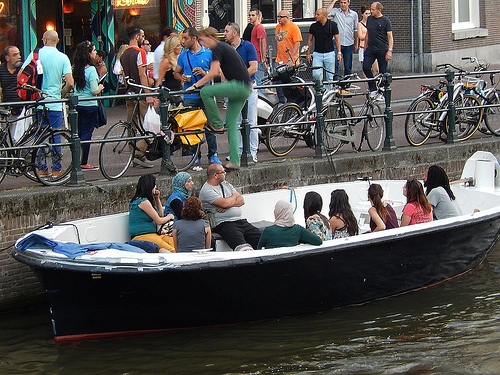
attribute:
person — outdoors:
[362, 4, 395, 93]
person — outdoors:
[15, 29, 74, 178]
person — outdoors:
[73, 40, 107, 171]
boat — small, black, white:
[10, 151, 499, 340]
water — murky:
[2, 238, 498, 374]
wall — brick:
[0, 201, 133, 300]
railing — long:
[0, 68, 499, 189]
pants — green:
[198, 79, 253, 167]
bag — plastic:
[142, 107, 161, 134]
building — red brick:
[350, 1, 498, 73]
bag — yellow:
[174, 107, 207, 146]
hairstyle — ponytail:
[368, 182, 394, 226]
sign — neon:
[114, 0, 151, 9]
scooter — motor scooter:
[253, 95, 273, 144]